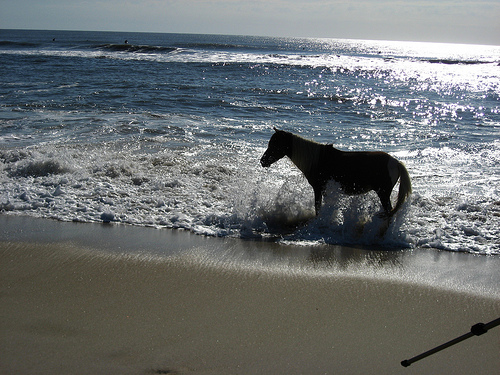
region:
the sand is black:
[318, 333, 337, 350]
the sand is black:
[299, 315, 314, 327]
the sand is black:
[268, 340, 281, 350]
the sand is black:
[298, 330, 320, 345]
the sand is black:
[269, 293, 282, 318]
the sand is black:
[297, 303, 318, 355]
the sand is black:
[246, 349, 256, 373]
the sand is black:
[292, 350, 306, 360]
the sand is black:
[279, 365, 290, 373]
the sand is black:
[284, 326, 303, 349]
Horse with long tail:
[247, 117, 442, 264]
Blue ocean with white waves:
[20, 1, 499, 291]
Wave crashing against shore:
[213, 168, 423, 249]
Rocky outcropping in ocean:
[62, 30, 225, 77]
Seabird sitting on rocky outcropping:
[108, 35, 142, 55]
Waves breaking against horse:
[273, 165, 389, 242]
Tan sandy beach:
[6, 230, 496, 366]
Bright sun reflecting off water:
[294, 27, 498, 127]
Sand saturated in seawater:
[3, 192, 499, 317]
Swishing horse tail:
[391, 153, 428, 238]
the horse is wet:
[269, 108, 421, 276]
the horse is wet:
[250, 67, 425, 359]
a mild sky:
[7, 0, 498, 44]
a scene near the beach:
[10, 8, 493, 339]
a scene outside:
[7, 2, 499, 369]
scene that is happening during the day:
[2, 7, 465, 371]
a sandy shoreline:
[5, 205, 495, 373]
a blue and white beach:
[6, 30, 490, 235]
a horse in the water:
[242, 118, 449, 263]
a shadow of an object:
[381, 295, 497, 374]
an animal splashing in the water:
[237, 89, 435, 301]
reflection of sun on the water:
[272, 27, 499, 104]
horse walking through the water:
[250, 115, 430, 257]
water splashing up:
[258, 180, 308, 218]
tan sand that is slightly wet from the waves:
[8, 231, 498, 373]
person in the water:
[124, 36, 135, 50]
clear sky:
[1, 0, 497, 41]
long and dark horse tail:
[395, 160, 411, 221]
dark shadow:
[385, 297, 496, 367]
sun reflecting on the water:
[375, 37, 497, 87]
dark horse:
[250, 105, 438, 237]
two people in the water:
[39, 26, 149, 54]